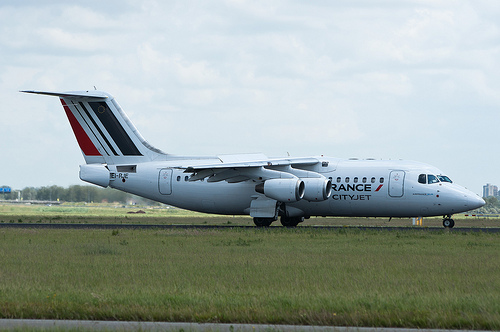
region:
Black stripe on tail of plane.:
[96, 105, 138, 167]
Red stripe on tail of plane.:
[63, 113, 114, 160]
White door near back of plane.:
[157, 161, 173, 208]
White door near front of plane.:
[382, 160, 419, 239]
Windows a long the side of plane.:
[199, 161, 374, 193]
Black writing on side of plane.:
[325, 172, 367, 204]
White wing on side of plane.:
[148, 144, 333, 205]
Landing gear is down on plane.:
[253, 203, 471, 230]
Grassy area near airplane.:
[171, 240, 346, 297]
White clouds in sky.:
[185, 37, 382, 102]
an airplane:
[21, 80, 481, 267]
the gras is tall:
[141, 246, 406, 296]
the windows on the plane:
[343, 172, 383, 182]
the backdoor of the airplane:
[155, 165, 176, 193]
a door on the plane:
[385, 170, 406, 200]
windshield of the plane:
[415, 172, 442, 182]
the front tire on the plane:
[438, 207, 453, 228]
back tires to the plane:
[250, 215, 295, 227]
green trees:
[45, 181, 87, 201]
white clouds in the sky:
[206, 38, 388, 130]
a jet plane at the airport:
[6, 81, 490, 237]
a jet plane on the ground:
[21, 77, 486, 250]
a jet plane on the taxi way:
[14, 75, 488, 257]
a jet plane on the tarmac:
[18, 82, 490, 235]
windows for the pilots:
[412, 167, 457, 189]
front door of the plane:
[381, 160, 408, 201]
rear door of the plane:
[148, 160, 180, 210]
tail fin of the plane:
[15, 80, 175, 159]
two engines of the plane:
[248, 166, 333, 211]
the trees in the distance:
[0, 181, 102, 209]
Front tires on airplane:
[439, 212, 456, 232]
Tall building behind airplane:
[482, 174, 497, 211]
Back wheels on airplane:
[242, 204, 314, 239]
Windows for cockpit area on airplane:
[416, 163, 459, 193]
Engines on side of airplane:
[249, 164, 336, 210]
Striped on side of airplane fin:
[69, 104, 134, 160]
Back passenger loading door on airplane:
[156, 166, 180, 201]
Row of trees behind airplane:
[17, 181, 91, 201]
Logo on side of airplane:
[330, 181, 372, 203]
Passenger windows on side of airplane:
[331, 174, 384, 184]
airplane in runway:
[19, 88, 486, 228]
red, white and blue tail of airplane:
[18, 91, 157, 160]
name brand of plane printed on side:
[328, 180, 383, 206]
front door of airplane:
[387, 170, 404, 197]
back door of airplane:
[159, 169, 175, 201]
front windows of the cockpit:
[418, 173, 456, 186]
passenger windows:
[329, 172, 386, 184]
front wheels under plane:
[442, 212, 457, 227]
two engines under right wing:
[257, 176, 332, 203]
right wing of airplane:
[155, 156, 325, 181]